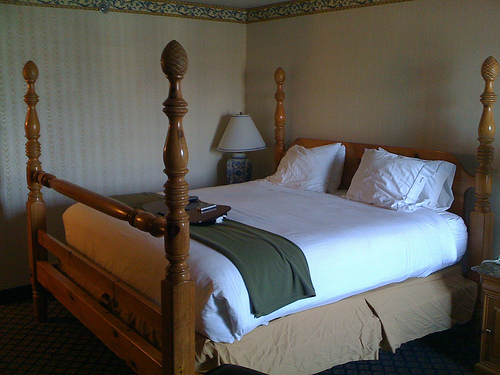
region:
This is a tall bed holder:
[153, 34, 208, 374]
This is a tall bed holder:
[15, 49, 66, 314]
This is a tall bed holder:
[268, 56, 298, 182]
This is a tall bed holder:
[474, 41, 497, 286]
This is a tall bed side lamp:
[209, 107, 279, 189]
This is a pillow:
[347, 141, 454, 233]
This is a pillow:
[262, 137, 342, 191]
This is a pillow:
[262, 131, 465, 250]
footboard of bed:
[19, 33, 194, 370]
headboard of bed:
[267, 54, 496, 296]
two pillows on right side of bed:
[345, 143, 450, 223]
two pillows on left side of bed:
[273, 138, 345, 192]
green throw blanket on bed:
[102, 189, 317, 323]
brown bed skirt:
[193, 262, 473, 374]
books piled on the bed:
[140, 194, 232, 233]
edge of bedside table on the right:
[465, 246, 499, 371]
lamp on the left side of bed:
[215, 102, 265, 188]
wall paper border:
[1, 0, 415, 28]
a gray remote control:
[192, 199, 217, 212]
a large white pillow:
[347, 148, 425, 212]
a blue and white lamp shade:
[215, 104, 267, 153]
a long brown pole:
[37, 166, 169, 239]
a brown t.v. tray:
[143, 193, 232, 225]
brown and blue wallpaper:
[243, 0, 365, 25]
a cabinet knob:
[485, 327, 492, 336]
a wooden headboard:
[291, 133, 478, 263]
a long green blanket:
[117, 186, 319, 316]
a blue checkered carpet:
[327, 329, 475, 374]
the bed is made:
[17, 34, 498, 374]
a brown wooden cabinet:
[470, 260, 496, 371]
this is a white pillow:
[343, 146, 435, 217]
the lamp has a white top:
[217, 109, 267, 181]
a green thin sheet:
[193, 217, 315, 323]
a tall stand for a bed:
[158, 36, 192, 373]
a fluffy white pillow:
[268, 144, 340, 195]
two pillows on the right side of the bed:
[342, 144, 457, 211]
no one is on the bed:
[52, 135, 478, 361]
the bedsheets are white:
[255, 191, 325, 232]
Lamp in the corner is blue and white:
[217, 109, 267, 184]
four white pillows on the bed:
[274, 150, 440, 215]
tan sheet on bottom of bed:
[310, 295, 447, 332]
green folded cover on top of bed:
[201, 236, 316, 303]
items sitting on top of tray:
[178, 192, 223, 225]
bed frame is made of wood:
[24, 42, 190, 319]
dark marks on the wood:
[107, 324, 142, 370]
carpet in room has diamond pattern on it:
[21, 339, 86, 366]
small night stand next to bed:
[470, 254, 499, 371]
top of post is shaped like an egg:
[155, 37, 192, 77]